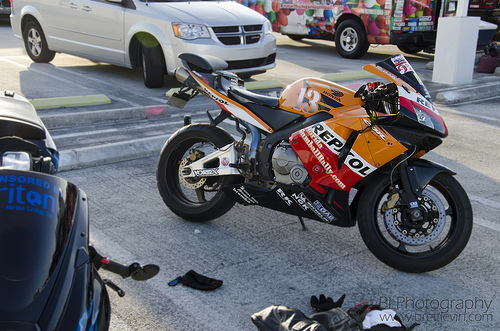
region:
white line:
[52, 71, 94, 95]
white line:
[67, 72, 135, 117]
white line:
[42, 57, 130, 132]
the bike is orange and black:
[103, 28, 432, 265]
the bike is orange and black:
[242, 48, 469, 317]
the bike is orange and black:
[150, 73, 378, 329]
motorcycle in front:
[71, 28, 448, 245]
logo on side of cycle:
[304, 112, 376, 173]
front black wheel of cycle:
[262, 160, 467, 288]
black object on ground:
[177, 240, 239, 307]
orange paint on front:
[268, 65, 363, 123]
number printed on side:
[294, 81, 342, 131]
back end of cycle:
[144, 57, 269, 148]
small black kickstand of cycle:
[291, 218, 312, 233]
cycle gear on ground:
[310, 278, 380, 323]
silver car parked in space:
[18, 11, 292, 68]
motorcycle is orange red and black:
[165, 36, 470, 240]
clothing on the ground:
[172, 257, 424, 322]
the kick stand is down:
[290, 185, 316, 242]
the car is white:
[8, 1, 295, 93]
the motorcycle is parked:
[158, 36, 474, 276]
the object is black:
[4, 164, 131, 324]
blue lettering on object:
[1, 171, 63, 238]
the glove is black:
[310, 287, 350, 311]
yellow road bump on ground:
[28, 90, 118, 127]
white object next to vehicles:
[433, 3, 475, 110]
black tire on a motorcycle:
[152, 117, 243, 228]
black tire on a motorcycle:
[347, 151, 478, 283]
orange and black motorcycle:
[145, 35, 488, 275]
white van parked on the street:
[0, 0, 289, 86]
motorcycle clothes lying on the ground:
[242, 286, 415, 330]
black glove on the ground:
[164, 256, 226, 299]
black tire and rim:
[326, 14, 378, 60]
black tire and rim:
[20, 14, 53, 64]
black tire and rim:
[130, 31, 170, 91]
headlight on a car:
[166, 16, 211, 47]